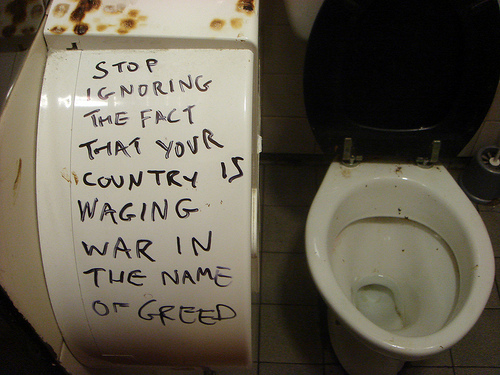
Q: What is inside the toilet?
A: Water.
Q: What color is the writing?
A: Black.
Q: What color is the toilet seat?
A: Black.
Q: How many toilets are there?
A: One.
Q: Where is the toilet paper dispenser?
A: Next to the toilet.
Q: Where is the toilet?
A: On the floor.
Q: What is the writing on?
A: A toilet paper dispenser.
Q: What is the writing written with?
A: Black marker.